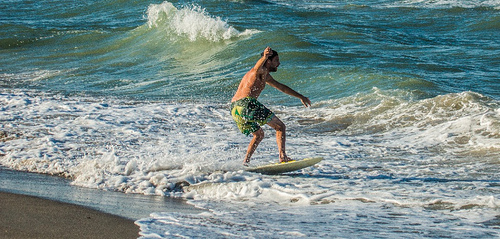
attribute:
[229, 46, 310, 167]
man — surfing, balancing, shirtless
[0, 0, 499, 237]
ocean — blue, shallow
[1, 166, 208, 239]
shore — sandy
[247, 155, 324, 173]
surfboard — white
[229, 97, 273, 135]
swim trunks — green, multicolored, blue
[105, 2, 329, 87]
wave — white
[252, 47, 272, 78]
arm — raised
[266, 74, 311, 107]
arm — extended